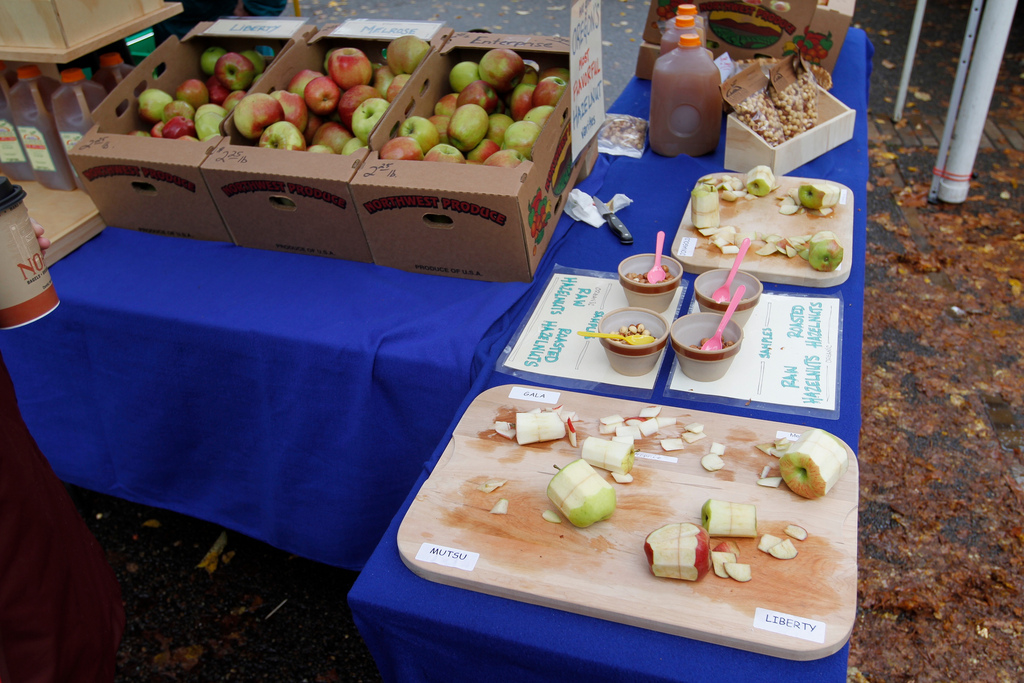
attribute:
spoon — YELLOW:
[578, 327, 661, 338]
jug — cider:
[645, 30, 725, 154]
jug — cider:
[653, 8, 706, 48]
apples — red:
[149, 6, 566, 292]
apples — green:
[87, 17, 602, 223]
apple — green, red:
[361, 96, 424, 148]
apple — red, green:
[400, 96, 444, 159]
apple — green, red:
[123, 77, 199, 149]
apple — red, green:
[205, 17, 264, 102]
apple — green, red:
[356, 118, 436, 185]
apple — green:
[542, 427, 648, 583]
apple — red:
[603, 520, 744, 627]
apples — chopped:
[518, 375, 773, 464]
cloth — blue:
[35, 187, 554, 572]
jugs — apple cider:
[603, 1, 759, 200]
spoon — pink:
[683, 241, 815, 350]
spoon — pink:
[633, 224, 683, 315]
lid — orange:
[652, 10, 711, 62]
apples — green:
[666, 140, 934, 277]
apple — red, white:
[637, 515, 741, 606]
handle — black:
[596, 189, 646, 256]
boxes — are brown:
[67, 24, 605, 286]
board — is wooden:
[389, 379, 861, 663]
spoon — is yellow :
[594, 329, 664, 343]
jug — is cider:
[641, 20, 728, 167]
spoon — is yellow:
[579, 323, 664, 360]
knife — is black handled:
[585, 193, 646, 260]